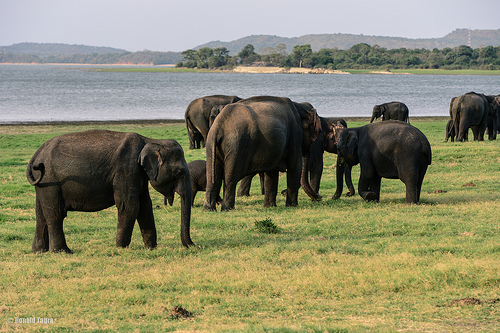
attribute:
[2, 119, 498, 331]
grass — brown, green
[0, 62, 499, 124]
water — blue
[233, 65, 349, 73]
sand — brown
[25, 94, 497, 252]
elephants — grazing, black, eating